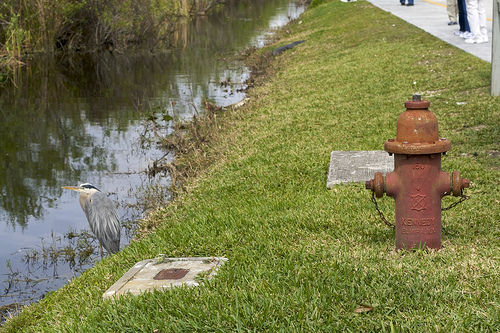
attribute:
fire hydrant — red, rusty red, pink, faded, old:
[364, 91, 472, 257]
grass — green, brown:
[4, 2, 498, 330]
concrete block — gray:
[102, 256, 227, 296]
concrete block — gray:
[323, 147, 400, 193]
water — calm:
[0, 1, 306, 317]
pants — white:
[466, 2, 493, 47]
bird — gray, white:
[59, 178, 122, 277]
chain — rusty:
[368, 192, 394, 234]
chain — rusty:
[442, 195, 470, 213]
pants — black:
[455, 2, 469, 40]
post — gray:
[489, 1, 499, 99]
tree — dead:
[51, 1, 105, 53]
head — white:
[64, 181, 103, 198]